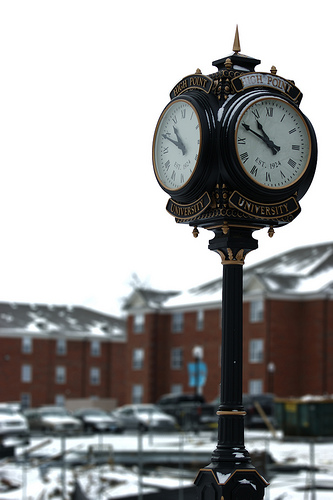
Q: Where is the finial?
A: At the top of the clock.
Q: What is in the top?
A: Clock.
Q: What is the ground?
A: Pole.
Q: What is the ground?
A: House.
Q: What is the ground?
A: Cars.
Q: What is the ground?
A: Vehicles.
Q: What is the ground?
A: Bricks.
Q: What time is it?
A: 10:50.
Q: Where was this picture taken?
A: High Point University.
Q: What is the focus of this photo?
A: The clock.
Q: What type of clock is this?
A: Analog.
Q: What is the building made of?
A: Bricks.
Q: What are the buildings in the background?
A: Dormitories.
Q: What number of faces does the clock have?
A: Four.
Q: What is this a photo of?
A: A clock.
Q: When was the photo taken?
A: Daytime.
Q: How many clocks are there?
A: Two.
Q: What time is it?
A: 10:49.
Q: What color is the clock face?
A: White.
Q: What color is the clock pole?
A: Black.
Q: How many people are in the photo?
A: None.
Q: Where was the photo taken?
A: On a street.